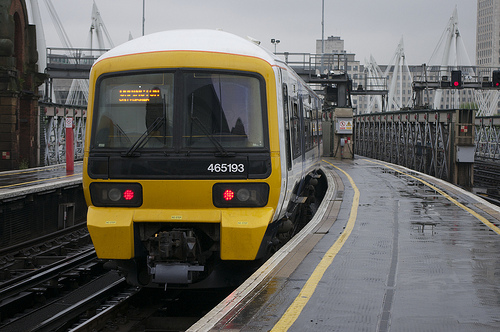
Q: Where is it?
A: This is at the train station.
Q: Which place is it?
A: It is a train station.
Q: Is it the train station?
A: Yes, it is the train station.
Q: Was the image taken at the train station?
A: Yes, it was taken in the train station.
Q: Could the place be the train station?
A: Yes, it is the train station.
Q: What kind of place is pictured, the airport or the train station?
A: It is the train station.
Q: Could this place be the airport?
A: No, it is the train station.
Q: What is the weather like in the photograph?
A: It is rainy.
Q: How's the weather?
A: It is rainy.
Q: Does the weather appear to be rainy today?
A: Yes, it is rainy.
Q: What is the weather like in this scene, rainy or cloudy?
A: It is rainy.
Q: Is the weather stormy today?
A: No, it is rainy.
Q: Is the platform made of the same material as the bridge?
A: No, the platform is made of cement and the bridge is made of metal.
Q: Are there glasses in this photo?
A: No, there are no glasses.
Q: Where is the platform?
A: The platform is in the train station.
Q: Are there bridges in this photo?
A: Yes, there is a bridge.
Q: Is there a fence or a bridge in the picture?
A: Yes, there is a bridge.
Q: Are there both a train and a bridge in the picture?
A: Yes, there are both a bridge and a train.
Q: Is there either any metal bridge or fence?
A: Yes, there is a metal bridge.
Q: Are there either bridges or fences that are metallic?
A: Yes, the bridge is metallic.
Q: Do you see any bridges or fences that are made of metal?
A: Yes, the bridge is made of metal.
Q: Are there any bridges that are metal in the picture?
A: Yes, there is a metal bridge.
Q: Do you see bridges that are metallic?
A: Yes, there is a bridge that is metallic.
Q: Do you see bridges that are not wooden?
A: Yes, there is a metallic bridge.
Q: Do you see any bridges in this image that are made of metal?
A: Yes, there is a bridge that is made of metal.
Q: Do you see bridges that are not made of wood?
A: Yes, there is a bridge that is made of metal.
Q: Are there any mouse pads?
A: No, there are no mouse pads.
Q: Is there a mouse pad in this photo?
A: No, there are no mouse pads.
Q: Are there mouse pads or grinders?
A: No, there are no mouse pads or grinders.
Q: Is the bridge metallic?
A: Yes, the bridge is metallic.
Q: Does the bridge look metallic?
A: Yes, the bridge is metallic.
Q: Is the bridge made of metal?
A: Yes, the bridge is made of metal.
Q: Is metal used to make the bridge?
A: Yes, the bridge is made of metal.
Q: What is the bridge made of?
A: The bridge is made of metal.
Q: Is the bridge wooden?
A: No, the bridge is metallic.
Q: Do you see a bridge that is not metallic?
A: No, there is a bridge but it is metallic.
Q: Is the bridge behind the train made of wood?
A: No, the bridge is made of metal.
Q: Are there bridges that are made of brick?
A: No, there is a bridge but it is made of metal.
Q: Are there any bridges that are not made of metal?
A: No, there is a bridge but it is made of metal.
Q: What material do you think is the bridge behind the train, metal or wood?
A: The bridge is made of metal.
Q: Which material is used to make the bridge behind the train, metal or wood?
A: The bridge is made of metal.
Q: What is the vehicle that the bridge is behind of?
A: The vehicle is a train.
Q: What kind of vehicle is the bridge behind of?
A: The bridge is behind the train.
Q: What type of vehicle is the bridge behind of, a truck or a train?
A: The bridge is behind a train.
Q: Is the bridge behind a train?
A: Yes, the bridge is behind a train.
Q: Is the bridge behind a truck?
A: No, the bridge is behind a train.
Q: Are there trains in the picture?
A: Yes, there is a train.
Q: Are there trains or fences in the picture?
A: Yes, there is a train.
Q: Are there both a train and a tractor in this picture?
A: No, there is a train but no tractors.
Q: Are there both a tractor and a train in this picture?
A: No, there is a train but no tractors.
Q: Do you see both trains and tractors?
A: No, there is a train but no tractors.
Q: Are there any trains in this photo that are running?
A: Yes, there is a train that is running.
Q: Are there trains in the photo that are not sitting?
A: Yes, there is a train that is running.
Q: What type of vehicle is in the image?
A: The vehicle is a train.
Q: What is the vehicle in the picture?
A: The vehicle is a train.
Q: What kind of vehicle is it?
A: The vehicle is a train.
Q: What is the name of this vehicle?
A: This is a train.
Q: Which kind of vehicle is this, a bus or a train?
A: This is a train.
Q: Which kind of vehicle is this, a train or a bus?
A: This is a train.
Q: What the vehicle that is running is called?
A: The vehicle is a train.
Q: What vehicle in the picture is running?
A: The vehicle is a train.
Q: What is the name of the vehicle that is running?
A: The vehicle is a train.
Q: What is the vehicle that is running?
A: The vehicle is a train.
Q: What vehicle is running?
A: The vehicle is a train.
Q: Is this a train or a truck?
A: This is a train.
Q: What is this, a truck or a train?
A: This is a train.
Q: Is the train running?
A: Yes, the train is running.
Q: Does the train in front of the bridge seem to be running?
A: Yes, the train is running.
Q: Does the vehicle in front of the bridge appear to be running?
A: Yes, the train is running.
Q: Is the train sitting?
A: No, the train is running.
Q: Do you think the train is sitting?
A: No, the train is running.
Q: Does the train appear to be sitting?
A: No, the train is running.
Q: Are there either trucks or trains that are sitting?
A: No, there is a train but it is running.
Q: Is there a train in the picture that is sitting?
A: No, there is a train but it is running.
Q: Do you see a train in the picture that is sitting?
A: No, there is a train but it is running.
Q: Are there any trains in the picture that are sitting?
A: No, there is a train but it is running.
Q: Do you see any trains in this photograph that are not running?
A: No, there is a train but it is running.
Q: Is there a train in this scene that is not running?
A: No, there is a train but it is running.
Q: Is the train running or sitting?
A: The train is running.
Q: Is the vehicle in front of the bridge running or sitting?
A: The train is running.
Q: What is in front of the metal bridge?
A: The train is in front of the bridge.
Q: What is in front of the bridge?
A: The train is in front of the bridge.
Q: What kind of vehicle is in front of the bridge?
A: The vehicle is a train.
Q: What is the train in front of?
A: The train is in front of the bridge.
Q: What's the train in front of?
A: The train is in front of the bridge.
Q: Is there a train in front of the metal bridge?
A: Yes, there is a train in front of the bridge.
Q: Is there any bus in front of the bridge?
A: No, there is a train in front of the bridge.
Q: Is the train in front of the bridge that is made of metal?
A: Yes, the train is in front of the bridge.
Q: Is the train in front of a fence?
A: No, the train is in front of the bridge.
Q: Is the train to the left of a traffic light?
A: Yes, the train is to the left of a traffic light.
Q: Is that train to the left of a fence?
A: No, the train is to the left of a traffic light.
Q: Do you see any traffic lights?
A: Yes, there is a traffic light.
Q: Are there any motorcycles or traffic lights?
A: Yes, there is a traffic light.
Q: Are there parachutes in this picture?
A: No, there are no parachutes.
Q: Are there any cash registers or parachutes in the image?
A: No, there are no parachutes or cash registers.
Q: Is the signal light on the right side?
A: Yes, the signal light is on the right of the image.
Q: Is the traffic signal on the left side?
A: No, the traffic signal is on the right of the image.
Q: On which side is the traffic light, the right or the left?
A: The traffic light is on the right of the image.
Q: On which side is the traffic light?
A: The traffic light is on the right of the image.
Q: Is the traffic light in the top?
A: Yes, the traffic light is in the top of the image.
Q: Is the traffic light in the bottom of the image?
A: No, the traffic light is in the top of the image.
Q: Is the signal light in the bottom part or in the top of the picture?
A: The signal light is in the top of the image.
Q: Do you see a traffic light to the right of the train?
A: Yes, there is a traffic light to the right of the train.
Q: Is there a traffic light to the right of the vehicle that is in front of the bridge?
A: Yes, there is a traffic light to the right of the train.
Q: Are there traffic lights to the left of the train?
A: No, the traffic light is to the right of the train.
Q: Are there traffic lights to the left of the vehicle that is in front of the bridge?
A: No, the traffic light is to the right of the train.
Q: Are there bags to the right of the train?
A: No, there is a traffic light to the right of the train.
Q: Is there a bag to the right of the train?
A: No, there is a traffic light to the right of the train.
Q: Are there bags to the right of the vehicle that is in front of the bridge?
A: No, there is a traffic light to the right of the train.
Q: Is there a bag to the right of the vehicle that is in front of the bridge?
A: No, there is a traffic light to the right of the train.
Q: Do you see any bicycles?
A: No, there are no bicycles.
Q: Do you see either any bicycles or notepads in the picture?
A: No, there are no bicycles or notepads.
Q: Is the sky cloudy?
A: Yes, the sky is cloudy.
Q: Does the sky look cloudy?
A: Yes, the sky is cloudy.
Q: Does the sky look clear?
A: No, the sky is cloudy.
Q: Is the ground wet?
A: Yes, the ground is wet.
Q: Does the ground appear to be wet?
A: Yes, the ground is wet.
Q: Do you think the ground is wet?
A: Yes, the ground is wet.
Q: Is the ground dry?
A: No, the ground is wet.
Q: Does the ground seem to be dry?
A: No, the ground is wet.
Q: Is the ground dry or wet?
A: The ground is wet.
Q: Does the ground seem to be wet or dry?
A: The ground is wet.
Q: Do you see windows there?
A: Yes, there is a window.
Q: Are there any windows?
A: Yes, there is a window.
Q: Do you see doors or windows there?
A: Yes, there is a window.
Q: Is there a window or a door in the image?
A: Yes, there is a window.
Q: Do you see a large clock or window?
A: Yes, there is a large window.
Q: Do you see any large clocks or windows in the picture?
A: Yes, there is a large window.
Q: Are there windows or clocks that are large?
A: Yes, the window is large.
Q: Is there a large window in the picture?
A: Yes, there is a large window.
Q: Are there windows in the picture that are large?
A: Yes, there is a window that is large.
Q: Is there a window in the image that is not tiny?
A: Yes, there is a large window.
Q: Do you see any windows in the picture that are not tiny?
A: Yes, there is a large window.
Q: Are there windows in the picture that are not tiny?
A: Yes, there is a large window.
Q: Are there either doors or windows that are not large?
A: No, there is a window but it is large.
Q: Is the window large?
A: Yes, the window is large.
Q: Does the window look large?
A: Yes, the window is large.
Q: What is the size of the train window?
A: The window is large.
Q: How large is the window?
A: The window is large.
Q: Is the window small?
A: No, the window is large.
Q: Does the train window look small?
A: No, the window is large.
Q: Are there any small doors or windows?
A: No, there is a window but it is large.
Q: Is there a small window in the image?
A: No, there is a window but it is large.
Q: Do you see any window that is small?
A: No, there is a window but it is large.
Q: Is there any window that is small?
A: No, there is a window but it is large.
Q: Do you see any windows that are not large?
A: No, there is a window but it is large.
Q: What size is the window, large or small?
A: The window is large.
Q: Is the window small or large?
A: The window is large.